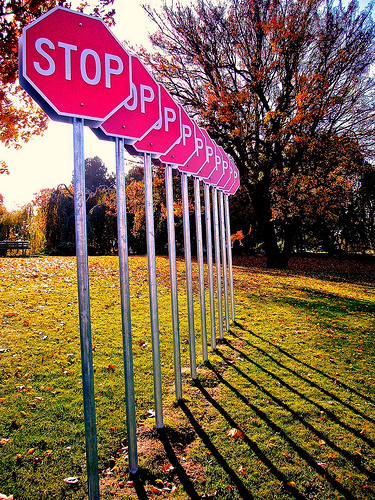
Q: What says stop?
A: The sign.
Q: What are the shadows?
A: Tall poles.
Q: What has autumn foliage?
A: The tall tree.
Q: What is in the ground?
A: Ten traffic stop signs.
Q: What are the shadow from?
A: The stop sign poles.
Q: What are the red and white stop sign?
A: Octagon.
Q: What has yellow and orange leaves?
A: The large tree.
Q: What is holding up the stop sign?
A: The metal pole.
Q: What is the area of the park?
A: Green grassy.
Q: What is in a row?
A: Stop signs.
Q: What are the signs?
A: Red and white.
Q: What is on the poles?
A: Stop signs.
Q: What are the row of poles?
A: Metallic.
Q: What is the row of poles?
A: Grey.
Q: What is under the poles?
A: Brown dirt.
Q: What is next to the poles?
A: Green grass.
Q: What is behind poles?
A: Tall tree.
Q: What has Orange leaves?
A: The tree.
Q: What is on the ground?
A: Shadows of the poles.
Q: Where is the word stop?
A: On the sign.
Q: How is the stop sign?
A: It is red.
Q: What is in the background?
A: Trees are in the background.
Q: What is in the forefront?
A: A red stop sign.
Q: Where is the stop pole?
A: In the forefront of the frame.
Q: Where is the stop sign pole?
A: Underneath the stop sign.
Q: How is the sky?
A: The sky is clear.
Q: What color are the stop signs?
A: Red.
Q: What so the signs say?
A: Stop.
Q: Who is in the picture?
A: No one.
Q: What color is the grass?
A: Green.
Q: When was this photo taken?
A: Daytime.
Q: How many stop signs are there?
A: 10.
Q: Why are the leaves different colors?
A: Fall season.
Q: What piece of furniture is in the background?
A: Bench.